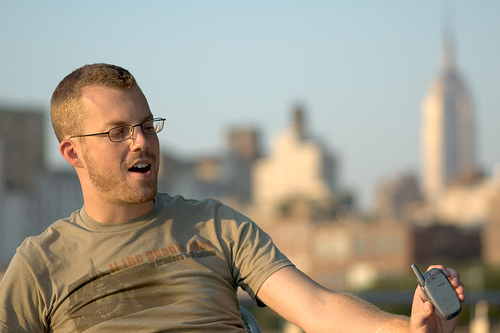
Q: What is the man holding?
A: A phone.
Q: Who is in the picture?
A: A man.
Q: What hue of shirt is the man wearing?
A: Brown.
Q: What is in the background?
A: New York City.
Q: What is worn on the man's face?
A: Eyeglasses.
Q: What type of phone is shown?
A: Flip phone.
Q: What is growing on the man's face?
A: Beard.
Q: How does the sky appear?
A: Blue and cloudless.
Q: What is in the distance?
A: View of New York City.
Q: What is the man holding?
A: A flip phone.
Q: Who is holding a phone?
A: The man.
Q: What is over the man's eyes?
A: Glasses.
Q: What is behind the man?
A: City skyline.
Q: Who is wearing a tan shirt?
A: The man.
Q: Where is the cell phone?
A: In the man's hand.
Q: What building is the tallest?
A: The one on the right.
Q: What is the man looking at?
A: His cell phone.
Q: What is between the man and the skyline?
A: A river.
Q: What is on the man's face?
A: Glasses.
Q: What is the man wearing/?
A: A t shirt.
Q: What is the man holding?
A: A cell phone.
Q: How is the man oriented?
A: Leaning left.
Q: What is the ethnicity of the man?
A: Caucasian..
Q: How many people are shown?
A: One.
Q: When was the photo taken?
A: Daytime.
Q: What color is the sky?
A: Blue.